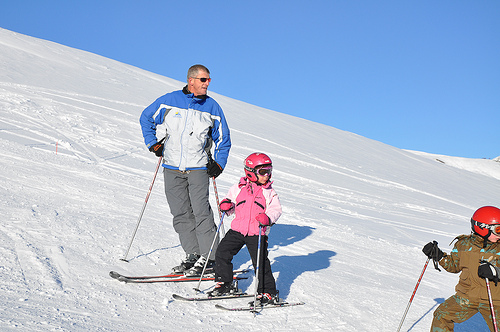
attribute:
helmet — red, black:
[467, 203, 498, 244]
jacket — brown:
[430, 234, 498, 330]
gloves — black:
[420, 239, 498, 285]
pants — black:
[214, 230, 276, 296]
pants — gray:
[162, 165, 220, 259]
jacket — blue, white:
[139, 86, 233, 171]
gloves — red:
[218, 198, 272, 227]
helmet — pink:
[242, 150, 271, 185]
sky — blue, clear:
[0, 1, 499, 159]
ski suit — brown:
[430, 231, 497, 330]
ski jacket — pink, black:
[228, 176, 282, 234]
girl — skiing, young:
[221, 153, 281, 305]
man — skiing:
[137, 63, 233, 275]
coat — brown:
[436, 233, 499, 291]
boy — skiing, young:
[422, 206, 499, 327]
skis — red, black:
[110, 266, 246, 285]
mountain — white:
[1, 24, 497, 330]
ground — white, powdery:
[4, 28, 498, 322]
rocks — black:
[433, 155, 445, 166]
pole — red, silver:
[396, 258, 497, 331]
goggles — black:
[189, 75, 210, 86]